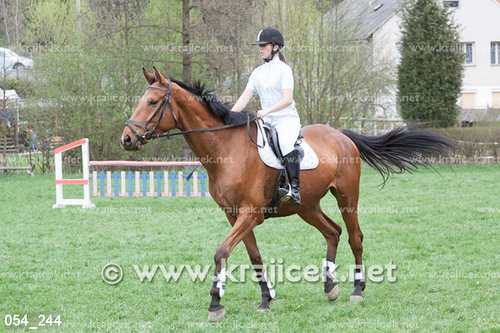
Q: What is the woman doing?
A: Riding.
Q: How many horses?
A: One.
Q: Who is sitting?
A: The woman.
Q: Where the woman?
A: In a field.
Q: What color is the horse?
A: Brown.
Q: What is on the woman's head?
A: Helmet.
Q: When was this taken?
A: During the day time.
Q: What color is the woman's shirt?
A: White.